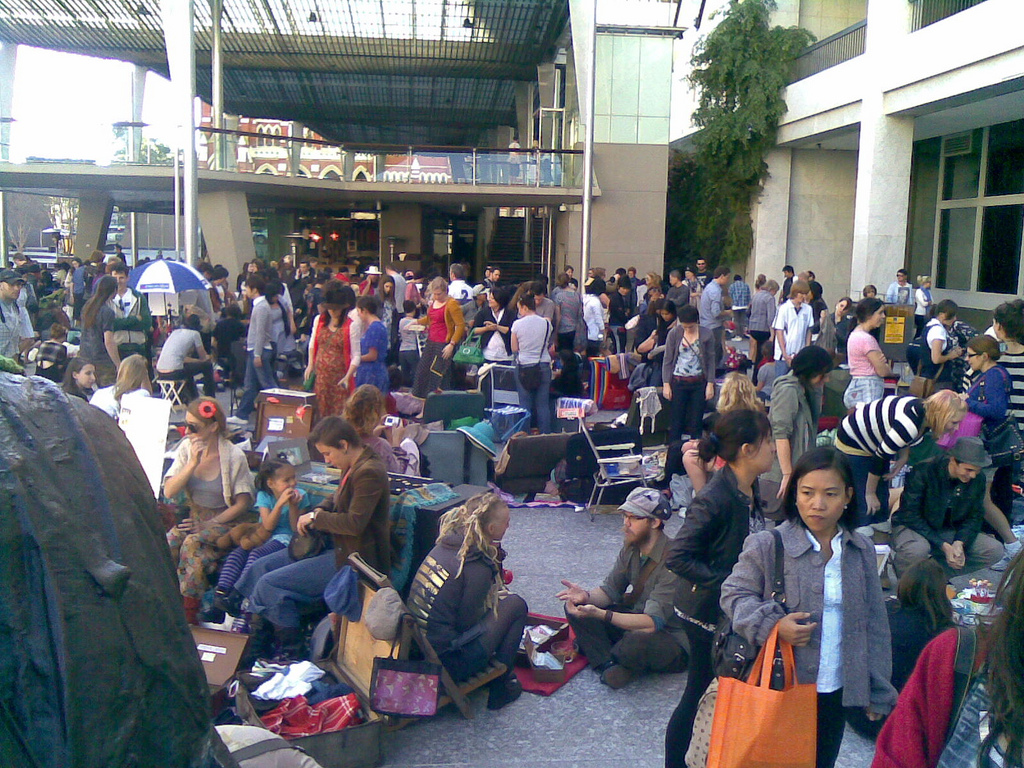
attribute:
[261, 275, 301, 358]
person — standing